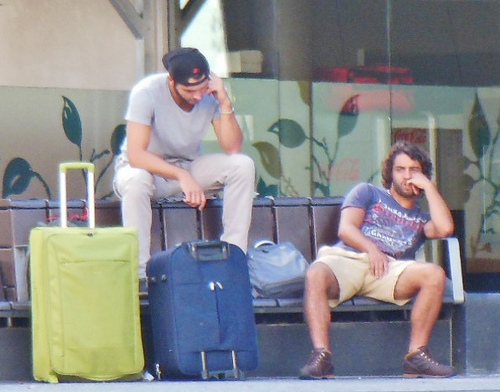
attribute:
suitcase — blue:
[149, 205, 265, 379]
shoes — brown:
[289, 334, 461, 390]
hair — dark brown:
[374, 137, 438, 191]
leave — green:
[61, 93, 86, 148]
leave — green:
[0, 156, 41, 201]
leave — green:
[270, 119, 305, 144]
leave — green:
[107, 121, 125, 153]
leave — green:
[252, 139, 284, 179]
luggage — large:
[148, 237, 264, 377]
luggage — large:
[28, 160, 147, 379]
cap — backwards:
[159, 40, 211, 95]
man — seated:
[292, 137, 463, 380]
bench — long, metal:
[6, 186, 492, 368]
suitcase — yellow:
[27, 225, 146, 382]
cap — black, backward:
[162, 40, 209, 92]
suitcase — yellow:
[149, 223, 301, 370]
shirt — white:
[111, 70, 220, 172]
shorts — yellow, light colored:
[313, 240, 413, 306]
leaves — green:
[269, 90, 359, 198]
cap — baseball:
[157, 43, 210, 86]